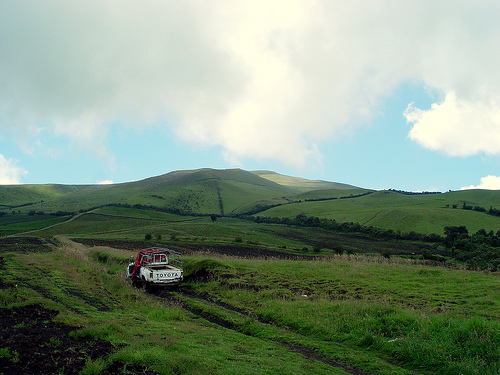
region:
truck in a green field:
[120, 231, 184, 307]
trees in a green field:
[297, 210, 392, 261]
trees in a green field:
[444, 190, 496, 226]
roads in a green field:
[22, 202, 82, 250]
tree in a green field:
[20, 289, 123, 371]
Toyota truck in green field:
[153, 270, 176, 284]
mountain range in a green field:
[35, 165, 478, 226]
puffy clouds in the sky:
[254, 38, 473, 170]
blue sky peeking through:
[26, 103, 189, 170]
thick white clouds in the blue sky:
[3, 3, 495, 166]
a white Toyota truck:
[123, 245, 186, 293]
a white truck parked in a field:
[125, 243, 185, 294]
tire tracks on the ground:
[151, 293, 363, 373]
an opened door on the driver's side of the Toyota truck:
[123, 258, 138, 281]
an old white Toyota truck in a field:
[4, 248, 495, 373]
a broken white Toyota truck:
[124, 243, 186, 294]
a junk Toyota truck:
[127, 244, 187, 294]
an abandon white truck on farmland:
[2, 230, 499, 373]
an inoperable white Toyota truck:
[123, 243, 186, 294]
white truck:
[132, 250, 182, 287]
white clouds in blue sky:
[13, 18, 57, 56]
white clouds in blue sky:
[32, 70, 113, 137]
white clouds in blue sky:
[42, 107, 137, 149]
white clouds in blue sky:
[131, 43, 218, 97]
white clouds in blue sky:
[123, 86, 201, 131]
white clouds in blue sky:
[245, 28, 372, 83]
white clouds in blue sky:
[313, 86, 405, 148]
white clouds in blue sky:
[415, 70, 489, 131]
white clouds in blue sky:
[316, 114, 394, 159]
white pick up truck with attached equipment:
[126, 245, 187, 289]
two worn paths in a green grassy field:
[160, 285, 431, 372]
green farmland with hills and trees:
[13, 167, 483, 367]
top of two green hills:
[105, 163, 426, 182]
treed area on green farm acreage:
[274, 208, 489, 274]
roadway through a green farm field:
[2, 205, 83, 237]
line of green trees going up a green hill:
[212, 179, 227, 218]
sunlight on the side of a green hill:
[256, 165, 331, 193]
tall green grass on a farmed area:
[266, 290, 485, 366]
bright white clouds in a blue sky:
[368, 93, 495, 189]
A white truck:
[114, 242, 191, 295]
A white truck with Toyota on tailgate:
[127, 242, 198, 283]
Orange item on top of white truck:
[132, 237, 162, 278]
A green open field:
[65, 262, 405, 353]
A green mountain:
[170, 161, 320, 246]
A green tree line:
[247, 211, 467, 256]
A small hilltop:
[320, 192, 476, 228]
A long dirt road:
[7, 210, 88, 237]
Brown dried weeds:
[315, 243, 465, 274]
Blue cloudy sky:
[88, 43, 498, 139]